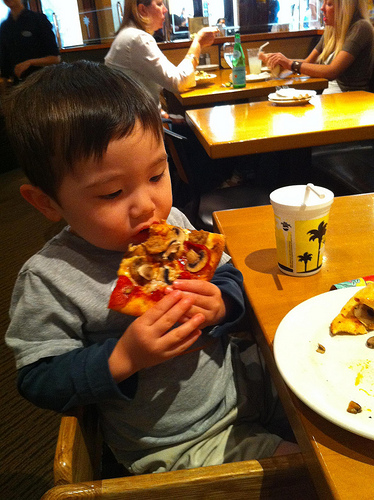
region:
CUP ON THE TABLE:
[277, 186, 333, 273]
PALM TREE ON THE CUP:
[311, 217, 328, 268]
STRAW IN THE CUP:
[311, 180, 321, 199]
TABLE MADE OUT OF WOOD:
[347, 225, 370, 253]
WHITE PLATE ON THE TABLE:
[313, 371, 327, 400]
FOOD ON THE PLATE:
[333, 290, 373, 346]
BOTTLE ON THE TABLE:
[236, 35, 243, 85]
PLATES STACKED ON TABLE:
[271, 97, 305, 105]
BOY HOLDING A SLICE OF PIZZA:
[116, 229, 224, 317]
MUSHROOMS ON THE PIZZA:
[184, 253, 206, 272]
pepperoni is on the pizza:
[86, 211, 247, 348]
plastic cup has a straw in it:
[251, 155, 362, 297]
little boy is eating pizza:
[26, 116, 239, 393]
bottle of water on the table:
[217, 21, 265, 90]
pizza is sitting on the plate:
[307, 253, 371, 349]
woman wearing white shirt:
[89, 19, 218, 111]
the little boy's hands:
[107, 278, 251, 372]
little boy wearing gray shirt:
[11, 270, 248, 455]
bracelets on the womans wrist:
[284, 56, 305, 77]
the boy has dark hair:
[8, 57, 169, 204]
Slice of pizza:
[102, 216, 229, 319]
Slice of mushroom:
[177, 243, 208, 270]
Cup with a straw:
[265, 178, 332, 275]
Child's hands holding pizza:
[104, 216, 226, 364]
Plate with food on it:
[268, 280, 369, 439]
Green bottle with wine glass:
[220, 27, 247, 88]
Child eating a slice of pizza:
[0, 53, 298, 491]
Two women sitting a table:
[98, 0, 365, 187]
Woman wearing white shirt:
[97, 0, 245, 197]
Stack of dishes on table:
[179, 80, 368, 159]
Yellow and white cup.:
[270, 181, 335, 276]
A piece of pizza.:
[108, 217, 227, 314]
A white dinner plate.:
[271, 283, 373, 439]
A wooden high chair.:
[43, 416, 318, 498]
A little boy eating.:
[2, 59, 302, 478]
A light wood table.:
[211, 190, 372, 498]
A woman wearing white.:
[104, 0, 219, 125]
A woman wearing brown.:
[267, 0, 373, 92]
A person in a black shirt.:
[0, 0, 61, 78]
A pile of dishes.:
[268, 83, 315, 104]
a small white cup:
[268, 179, 340, 273]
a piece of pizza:
[110, 230, 223, 315]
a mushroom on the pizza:
[184, 247, 208, 269]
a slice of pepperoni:
[110, 274, 133, 307]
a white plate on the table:
[276, 285, 372, 437]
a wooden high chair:
[37, 343, 315, 499]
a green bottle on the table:
[229, 35, 248, 84]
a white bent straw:
[303, 179, 324, 207]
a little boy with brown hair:
[9, 65, 190, 241]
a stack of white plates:
[265, 81, 316, 103]